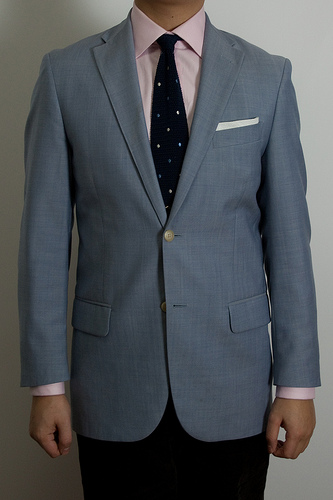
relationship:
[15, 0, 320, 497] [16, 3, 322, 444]
man wearing jacket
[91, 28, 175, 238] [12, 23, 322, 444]
lapel on suit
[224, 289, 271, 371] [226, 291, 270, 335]
pocket has flap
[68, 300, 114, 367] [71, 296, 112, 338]
pocket has flap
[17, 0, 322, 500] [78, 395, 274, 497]
man wearing pants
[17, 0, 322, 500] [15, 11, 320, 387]
man wearing jacket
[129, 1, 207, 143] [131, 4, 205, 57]
shirt has collar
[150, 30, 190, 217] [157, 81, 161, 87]
tie with polka dot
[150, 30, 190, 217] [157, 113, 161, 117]
tie with polka dot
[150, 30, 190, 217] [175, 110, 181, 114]
tie with polka dot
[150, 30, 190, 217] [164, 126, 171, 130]
tie with polka dot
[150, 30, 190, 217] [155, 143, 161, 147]
tie with polka dot